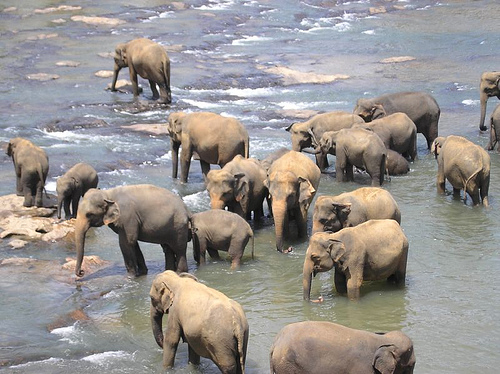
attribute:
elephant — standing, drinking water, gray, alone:
[109, 38, 172, 106]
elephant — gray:
[5, 136, 53, 208]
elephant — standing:
[54, 161, 99, 220]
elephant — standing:
[72, 183, 199, 279]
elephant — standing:
[150, 269, 253, 374]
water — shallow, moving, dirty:
[0, 0, 496, 373]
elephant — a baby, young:
[186, 209, 255, 271]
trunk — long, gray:
[72, 215, 89, 278]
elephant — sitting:
[382, 149, 414, 177]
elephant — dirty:
[263, 149, 322, 253]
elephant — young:
[302, 127, 392, 187]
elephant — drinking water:
[298, 218, 410, 301]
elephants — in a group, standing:
[3, 38, 498, 371]